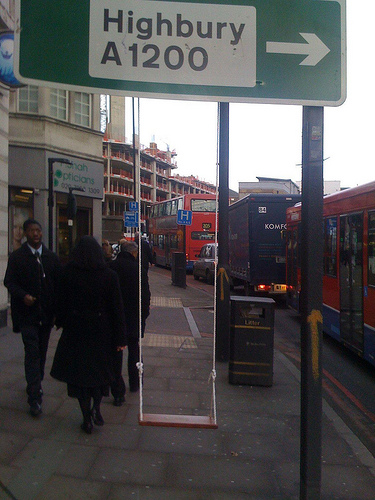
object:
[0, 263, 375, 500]
gray ground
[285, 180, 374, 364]
buses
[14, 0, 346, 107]
sign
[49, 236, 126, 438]
people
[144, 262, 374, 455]
road